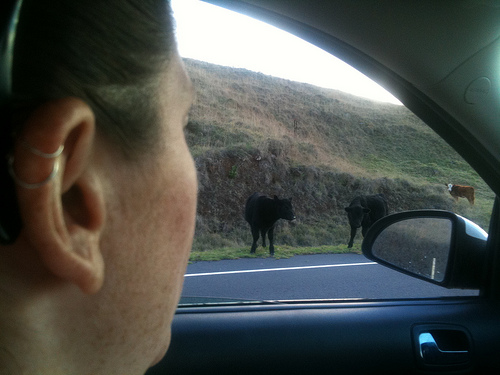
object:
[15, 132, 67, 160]
earring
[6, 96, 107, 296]
ear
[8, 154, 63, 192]
earring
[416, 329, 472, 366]
handle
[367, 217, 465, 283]
mirror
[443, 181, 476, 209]
cow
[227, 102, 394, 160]
grass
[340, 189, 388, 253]
cow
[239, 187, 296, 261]
cow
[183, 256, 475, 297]
street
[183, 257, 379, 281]
line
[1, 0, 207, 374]
girl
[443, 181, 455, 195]
head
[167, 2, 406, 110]
sky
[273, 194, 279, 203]
ear